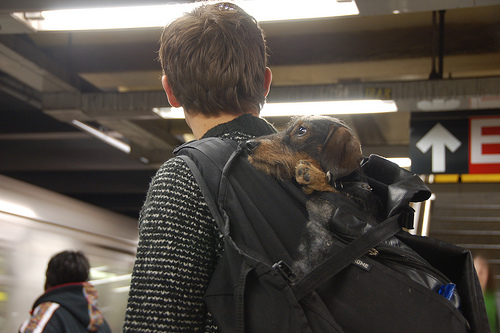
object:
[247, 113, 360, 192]
dog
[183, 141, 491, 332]
backpack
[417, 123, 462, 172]
arrow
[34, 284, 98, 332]
jacket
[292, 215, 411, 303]
strap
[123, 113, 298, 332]
sweater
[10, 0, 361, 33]
light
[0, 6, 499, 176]
ceiling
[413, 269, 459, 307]
tag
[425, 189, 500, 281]
stairs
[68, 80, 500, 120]
beam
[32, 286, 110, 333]
coat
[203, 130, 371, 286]
back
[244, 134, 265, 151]
nose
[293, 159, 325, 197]
paw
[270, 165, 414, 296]
carrier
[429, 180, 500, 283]
stripe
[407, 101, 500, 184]
sign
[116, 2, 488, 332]
boy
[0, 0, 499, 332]
airport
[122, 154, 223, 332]
sleeve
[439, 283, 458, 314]
pen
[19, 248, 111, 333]
person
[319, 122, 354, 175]
ear